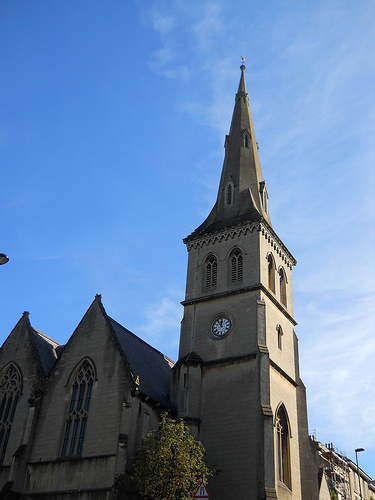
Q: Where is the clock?
A: In the tower.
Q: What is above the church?
A: The blue sky.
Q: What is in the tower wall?
A: A clock.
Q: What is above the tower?
A: A steeple.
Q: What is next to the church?
A: A tree.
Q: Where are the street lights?
A: Next to the church.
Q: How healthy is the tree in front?
A: Halfway dying.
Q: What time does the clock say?
A: 11:00.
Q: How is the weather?
A: Bright, sunny, and partly cloudy.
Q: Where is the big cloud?
A: Right side of sky.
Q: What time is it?
A: 11:55.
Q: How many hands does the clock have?
A: 2.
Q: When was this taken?
A: Daytime.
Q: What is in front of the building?
A: A tree.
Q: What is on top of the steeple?
A: A weathervane.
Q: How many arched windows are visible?
A: 11.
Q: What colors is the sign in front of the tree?
A: Red and white.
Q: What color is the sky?
A: Blue.